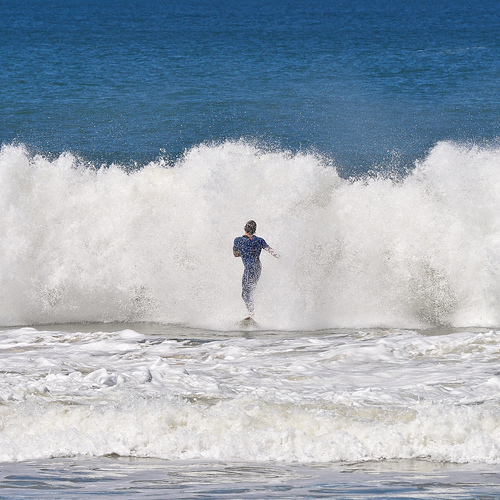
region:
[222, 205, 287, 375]
a person on a surfboard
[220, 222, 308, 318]
a black and blue wet suit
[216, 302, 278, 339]
a board on the water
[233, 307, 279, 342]
a surfboard with a person on it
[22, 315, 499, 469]
white foamy water from waves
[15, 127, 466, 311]
a large wave behind surfer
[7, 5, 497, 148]
pure blue water behind wave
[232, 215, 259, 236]
black hair on head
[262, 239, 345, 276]
an arm in the water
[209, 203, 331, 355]
a person surfing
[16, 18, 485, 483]
picture taken at ocean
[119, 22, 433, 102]
calm blue water behind wave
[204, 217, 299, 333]
person surfing in the ocean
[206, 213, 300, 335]
person wearing a blue wet suit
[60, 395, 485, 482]
white foam caused by crashing waves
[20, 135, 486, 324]
large wave crashing to shore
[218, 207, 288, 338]
person standing on surfboard as wave crashes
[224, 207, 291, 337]
surfing into wave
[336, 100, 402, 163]
ocean spray above wave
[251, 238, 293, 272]
persons are out to create balance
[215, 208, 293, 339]
man in front a wave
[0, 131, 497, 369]
a big white wave in the sea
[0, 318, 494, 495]
foamy water in the sea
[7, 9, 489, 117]
blue water in the sea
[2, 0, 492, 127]
this part of the sea is calm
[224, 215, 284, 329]
man wears a black suit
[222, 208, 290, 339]
surfer stands on a surfboard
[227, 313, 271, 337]
surfboard is color white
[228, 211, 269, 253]
hair of man is black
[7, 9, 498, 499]
a wave in the ocean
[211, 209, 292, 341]
PERSON ON A SURFBOARD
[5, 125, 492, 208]
SPRAY COMING UP FROM WAVE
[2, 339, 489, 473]
WAVE BREAKING IN FRONT OF SURFER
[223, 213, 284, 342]
SURFER RIDING THE WAVES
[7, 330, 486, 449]
WATER IS WHITE AND FROTHY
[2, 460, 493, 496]
WATER IS BLUE-GRAY IN THE FOREGROUND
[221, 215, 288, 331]
SURFER IS FACING AWAY FROM CAMERA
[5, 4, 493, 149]
WATER IS DEEP BLUE IN BACKGROUND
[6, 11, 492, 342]
THIS BODY OF WATER IS CALLED THE OCEAN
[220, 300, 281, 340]
MAN'S FEET ARE ON SURFBOARD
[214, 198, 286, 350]
a man is surfing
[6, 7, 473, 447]
the man is in the ocean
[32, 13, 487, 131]
this portion of the water is blue in color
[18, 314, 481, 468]
the portion of the water appears white in color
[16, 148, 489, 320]
the water is splashing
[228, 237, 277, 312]
the man is wearing a wet suit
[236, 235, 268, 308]
the mans wet suit is blue in color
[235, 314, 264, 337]
a portion of the surfboard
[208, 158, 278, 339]
the man is headed towards the wave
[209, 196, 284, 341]
the man is on the surfboard